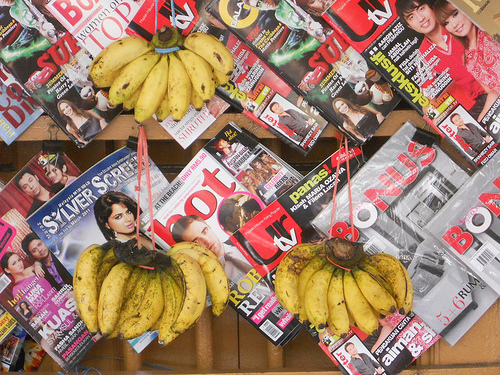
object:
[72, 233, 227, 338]
rot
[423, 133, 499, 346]
magazine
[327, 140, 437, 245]
word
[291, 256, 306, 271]
rot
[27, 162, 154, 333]
magazines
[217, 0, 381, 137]
magazines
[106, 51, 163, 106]
bananas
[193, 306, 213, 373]
dowel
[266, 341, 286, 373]
dowel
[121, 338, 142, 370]
dowel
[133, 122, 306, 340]
magazines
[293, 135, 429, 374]
magazines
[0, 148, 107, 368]
magazines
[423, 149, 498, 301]
magazines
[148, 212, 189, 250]
lettering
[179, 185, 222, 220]
lettering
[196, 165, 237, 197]
lettering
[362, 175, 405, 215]
lettering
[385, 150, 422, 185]
lettering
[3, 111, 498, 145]
board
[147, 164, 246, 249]
wor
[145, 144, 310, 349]
mag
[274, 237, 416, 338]
yellow banana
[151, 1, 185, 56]
string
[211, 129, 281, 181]
magazine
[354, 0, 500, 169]
magazine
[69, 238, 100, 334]
banana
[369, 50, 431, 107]
lettering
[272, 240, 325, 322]
banana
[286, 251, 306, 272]
spots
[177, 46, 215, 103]
yellow/ripe bananas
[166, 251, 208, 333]
yellow/ripe bananas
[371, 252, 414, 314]
yellow/ripe bananas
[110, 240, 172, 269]
tops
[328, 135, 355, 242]
string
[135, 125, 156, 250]
string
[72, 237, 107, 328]
bananas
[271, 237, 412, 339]
bunch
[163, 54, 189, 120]
banana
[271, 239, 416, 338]
banana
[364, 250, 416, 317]
banana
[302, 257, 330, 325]
banana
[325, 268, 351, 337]
banana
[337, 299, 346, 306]
spot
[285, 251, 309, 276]
spot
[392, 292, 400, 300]
spot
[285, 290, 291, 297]
spot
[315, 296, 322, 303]
spot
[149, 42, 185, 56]
tie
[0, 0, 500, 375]
newstand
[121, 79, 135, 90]
rot